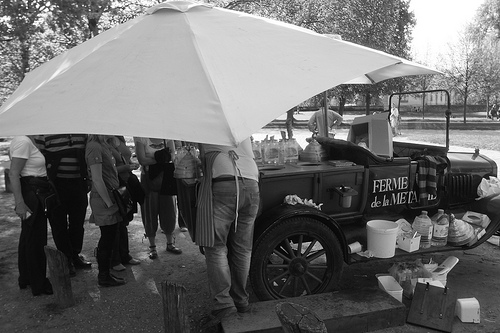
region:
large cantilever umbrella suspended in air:
[6, 5, 451, 161]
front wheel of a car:
[256, 217, 346, 310]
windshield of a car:
[379, 87, 466, 152]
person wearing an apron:
[195, 148, 248, 243]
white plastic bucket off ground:
[363, 216, 400, 264]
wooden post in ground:
[156, 276, 196, 331]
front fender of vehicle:
[250, 201, 355, 261]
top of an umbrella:
[128, 0, 208, 17]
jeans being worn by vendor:
[203, 178, 260, 330]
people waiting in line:
[5, 136, 216, 282]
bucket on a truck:
[361, 205, 398, 266]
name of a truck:
[367, 162, 434, 218]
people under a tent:
[10, 133, 275, 324]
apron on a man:
[192, 142, 228, 247]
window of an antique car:
[386, 89, 459, 144]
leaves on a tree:
[5, 13, 82, 97]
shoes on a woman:
[143, 247, 183, 264]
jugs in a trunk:
[262, 131, 332, 171]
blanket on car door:
[416, 147, 449, 201]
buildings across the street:
[418, 69, 486, 110]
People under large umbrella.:
[45, 49, 283, 219]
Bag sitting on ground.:
[395, 271, 471, 321]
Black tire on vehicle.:
[252, 217, 347, 274]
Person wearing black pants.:
[21, 240, 56, 279]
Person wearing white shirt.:
[14, 147, 36, 164]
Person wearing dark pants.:
[48, 195, 99, 237]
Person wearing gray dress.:
[79, 160, 114, 219]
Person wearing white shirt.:
[222, 148, 244, 180]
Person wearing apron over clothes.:
[191, 193, 225, 244]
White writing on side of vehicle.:
[376, 168, 433, 215]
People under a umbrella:
[13, 55, 306, 327]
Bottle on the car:
[416, 211, 433, 247]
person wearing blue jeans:
[196, 171, 259, 311]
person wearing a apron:
[188, 143, 220, 253]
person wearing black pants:
[88, 217, 120, 277]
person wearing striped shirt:
[37, 133, 91, 193]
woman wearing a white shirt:
[3, 134, 55, 181]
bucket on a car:
[356, 212, 403, 264]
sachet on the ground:
[403, 273, 448, 328]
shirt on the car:
[413, 148, 440, 200]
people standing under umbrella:
[35, 33, 351, 259]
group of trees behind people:
[2, 12, 462, 104]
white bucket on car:
[365, 205, 400, 253]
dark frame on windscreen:
[385, 80, 454, 205]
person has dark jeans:
[199, 178, 264, 313]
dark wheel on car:
[238, 218, 352, 299]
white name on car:
[367, 153, 413, 200]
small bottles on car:
[247, 128, 317, 161]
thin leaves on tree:
[6, 10, 113, 56]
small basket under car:
[390, 256, 476, 331]